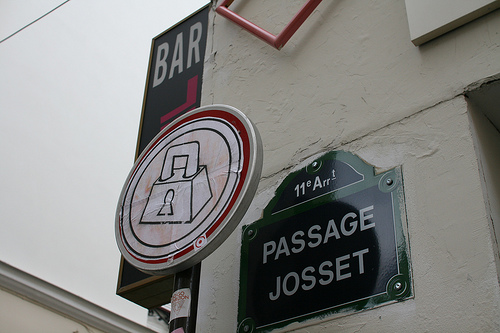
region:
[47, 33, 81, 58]
white clouds in blue sky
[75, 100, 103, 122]
white clouds in blue sky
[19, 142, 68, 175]
white clouds in blue sky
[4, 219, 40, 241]
white clouds in blue sky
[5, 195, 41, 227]
white clouds in blue sky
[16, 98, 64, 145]
white clouds in blue sky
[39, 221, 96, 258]
white clouds in blue sky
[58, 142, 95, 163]
white clouds in blue sky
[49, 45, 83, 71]
white clouds in blue sky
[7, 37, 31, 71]
white clouds in blue sky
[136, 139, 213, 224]
A lock on a sign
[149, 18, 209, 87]
BAR on a sign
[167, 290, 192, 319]
White sticker on a pole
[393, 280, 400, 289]
Bolt holding a sign to a building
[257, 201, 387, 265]
PASSAGE on a sign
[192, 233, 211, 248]
Red bulls eye on a sign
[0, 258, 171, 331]
Gutter on a roof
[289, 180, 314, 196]
11e on a sign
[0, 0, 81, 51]
Wire above a building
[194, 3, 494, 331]
White wall on a building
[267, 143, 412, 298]
black and white sign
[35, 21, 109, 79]
white clouds in blue sky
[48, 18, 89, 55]
white clouds in blue sky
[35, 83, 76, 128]
white clouds in blue sky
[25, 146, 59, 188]
white clouds in blue sky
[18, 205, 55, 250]
white clouds in blue sky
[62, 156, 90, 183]
white clouds in blue sky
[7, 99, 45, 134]
white clouds in blue sky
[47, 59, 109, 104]
white clouds in blue sky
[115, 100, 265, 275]
Sign with picture of lock on it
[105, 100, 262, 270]
Red and white sign on pole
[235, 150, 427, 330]
Black and green sign on building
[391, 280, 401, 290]
Metal fastner holding sign on building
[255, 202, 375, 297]
White lettering on sign on building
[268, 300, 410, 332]
Gray paint over green paint on sign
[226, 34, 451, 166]
Uneven texture on building wall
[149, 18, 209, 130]
Gray lettering and red design on building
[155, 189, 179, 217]
Keyhole in front of lock picture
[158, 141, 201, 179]
Black handle on top of lock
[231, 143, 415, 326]
green, black, and silver street sign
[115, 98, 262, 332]
caution sign with lock sticker on top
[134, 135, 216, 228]
image of a lock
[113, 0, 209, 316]
bar sign on building side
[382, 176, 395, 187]
screw on top right corner of sign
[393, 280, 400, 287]
screw on bottom right corner of sign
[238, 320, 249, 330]
screw on bottom left corner of sign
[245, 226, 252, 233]
screw on top left corner of sign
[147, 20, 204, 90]
the word "Bar" on building sign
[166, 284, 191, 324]
sticker taped to caution pole